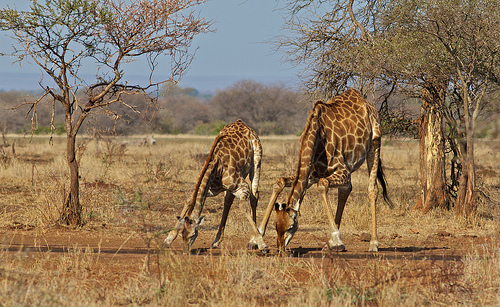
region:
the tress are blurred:
[135, 77, 375, 154]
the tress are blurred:
[146, 82, 244, 119]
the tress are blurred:
[115, 55, 273, 167]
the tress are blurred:
[155, 54, 273, 128]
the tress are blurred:
[153, 48, 353, 220]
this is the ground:
[83, 238, 113, 254]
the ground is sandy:
[61, 230, 101, 257]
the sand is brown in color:
[72, 239, 99, 246]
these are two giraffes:
[153, 84, 405, 241]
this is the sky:
[218, 5, 255, 60]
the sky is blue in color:
[229, 17, 264, 77]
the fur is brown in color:
[303, 135, 350, 152]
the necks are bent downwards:
[190, 160, 310, 243]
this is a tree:
[372, 0, 487, 215]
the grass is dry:
[174, 281, 270, 305]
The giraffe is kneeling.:
[260, 100, 419, 256]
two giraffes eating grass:
[150, 96, 422, 278]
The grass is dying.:
[33, 219, 482, 304]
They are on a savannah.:
[17, 11, 499, 300]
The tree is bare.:
[310, 10, 498, 218]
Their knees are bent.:
[143, 179, 414, 261]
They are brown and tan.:
[135, 82, 430, 228]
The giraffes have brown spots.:
[124, 83, 432, 300]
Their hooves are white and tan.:
[254, 213, 403, 257]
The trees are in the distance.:
[15, 68, 422, 146]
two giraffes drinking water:
[153, 74, 413, 267]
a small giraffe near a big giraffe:
[162, 112, 354, 274]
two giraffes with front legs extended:
[158, 83, 401, 285]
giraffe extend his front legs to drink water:
[155, 112, 277, 266]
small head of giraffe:
[168, 210, 215, 257]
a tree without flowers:
[5, 3, 172, 231]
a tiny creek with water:
[3, 238, 498, 258]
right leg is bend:
[315, 163, 360, 257]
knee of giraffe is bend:
[264, 171, 294, 204]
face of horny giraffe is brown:
[264, 193, 306, 250]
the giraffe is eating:
[165, 101, 365, 301]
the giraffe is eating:
[190, 151, 257, 249]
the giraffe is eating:
[153, 110, 255, 305]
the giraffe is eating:
[186, 108, 287, 298]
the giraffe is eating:
[160, 67, 234, 238]